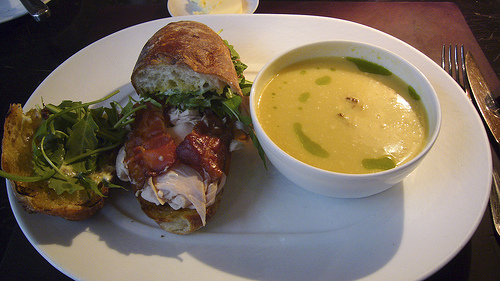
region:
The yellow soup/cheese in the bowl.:
[280, 50, 418, 161]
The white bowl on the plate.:
[249, 34, 449, 201]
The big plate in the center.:
[5, 14, 498, 279]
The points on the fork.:
[442, 45, 469, 80]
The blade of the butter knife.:
[460, 53, 496, 129]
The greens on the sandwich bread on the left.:
[29, 103, 109, 195]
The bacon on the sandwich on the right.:
[130, 110, 231, 180]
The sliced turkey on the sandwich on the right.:
[118, 118, 215, 204]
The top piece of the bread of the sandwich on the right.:
[129, 18, 237, 100]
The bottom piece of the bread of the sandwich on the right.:
[144, 208, 218, 233]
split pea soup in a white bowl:
[258, 51, 438, 174]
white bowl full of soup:
[251, 35, 440, 199]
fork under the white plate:
[439, 43, 499, 231]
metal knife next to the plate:
[464, 45, 499, 149]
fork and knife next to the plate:
[441, 45, 499, 237]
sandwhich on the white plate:
[8, 18, 250, 228]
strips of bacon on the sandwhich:
[123, 104, 233, 185]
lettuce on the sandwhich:
[18, 37, 257, 199]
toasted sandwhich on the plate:
[3, 20, 250, 237]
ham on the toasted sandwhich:
[116, 107, 228, 217]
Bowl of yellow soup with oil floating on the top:
[259, 30, 440, 221]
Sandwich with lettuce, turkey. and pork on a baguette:
[116, 13, 247, 250]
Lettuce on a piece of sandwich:
[38, 96, 122, 201]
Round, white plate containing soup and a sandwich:
[1, 20, 486, 279]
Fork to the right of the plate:
[436, 28, 468, 94]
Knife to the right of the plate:
[466, 43, 497, 173]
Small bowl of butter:
[161, 0, 268, 16]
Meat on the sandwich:
[128, 96, 232, 230]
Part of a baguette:
[143, 10, 244, 122]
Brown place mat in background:
[271, 3, 497, 81]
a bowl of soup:
[243, 43, 448, 177]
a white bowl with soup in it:
[241, 23, 488, 210]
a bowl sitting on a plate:
[236, 6, 480, 208]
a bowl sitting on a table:
[230, 8, 467, 224]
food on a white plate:
[27, 0, 403, 273]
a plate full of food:
[73, 0, 470, 263]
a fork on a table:
[436, 47, 499, 118]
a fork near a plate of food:
[439, 24, 489, 159]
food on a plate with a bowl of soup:
[63, 8, 351, 240]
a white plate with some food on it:
[57, 3, 469, 229]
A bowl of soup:
[311, 78, 388, 158]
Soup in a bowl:
[312, 91, 382, 131]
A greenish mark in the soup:
[306, 141, 311, 148]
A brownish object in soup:
[348, 98, 358, 101]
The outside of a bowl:
[313, 180, 366, 190]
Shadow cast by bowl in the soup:
[389, 77, 396, 85]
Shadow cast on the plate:
[302, 203, 359, 221]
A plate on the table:
[445, 128, 457, 211]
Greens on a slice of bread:
[38, 135, 86, 159]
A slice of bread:
[7, 138, 24, 163]